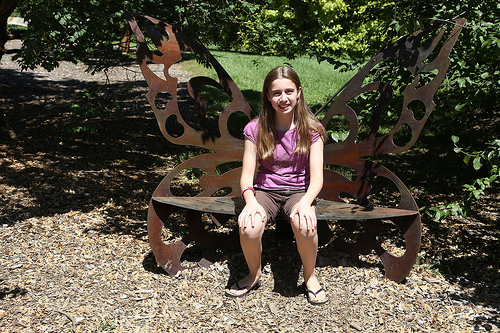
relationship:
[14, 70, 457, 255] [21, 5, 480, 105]
shadow of tree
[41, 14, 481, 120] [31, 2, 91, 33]
tree with branch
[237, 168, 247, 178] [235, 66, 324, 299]
elbow of girl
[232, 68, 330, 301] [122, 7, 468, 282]
girl sitting on butterfly bench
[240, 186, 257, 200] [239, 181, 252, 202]
bracelet on wrist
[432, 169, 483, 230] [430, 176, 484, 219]
branch with leaves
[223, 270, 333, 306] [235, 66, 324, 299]
feet of girl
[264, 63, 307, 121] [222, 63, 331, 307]
head of girl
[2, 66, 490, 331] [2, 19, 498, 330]
shadows on ground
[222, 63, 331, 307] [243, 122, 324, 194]
girl wearing tee shirt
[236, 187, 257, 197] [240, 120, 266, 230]
bracelet around arm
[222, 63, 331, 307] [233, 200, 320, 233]
girl has hands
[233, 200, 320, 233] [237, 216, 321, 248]
hands on knees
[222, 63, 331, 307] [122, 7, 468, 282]
girl sitting on butterfly bench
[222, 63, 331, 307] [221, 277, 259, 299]
girl wearing slipper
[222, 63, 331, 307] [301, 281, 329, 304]
girl wearing slipper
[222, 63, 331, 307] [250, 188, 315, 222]
girl wearing shorts